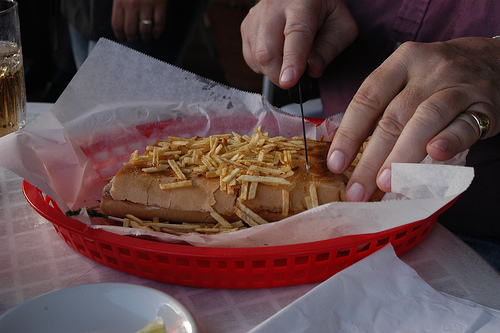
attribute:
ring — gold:
[470, 110, 492, 141]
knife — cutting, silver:
[296, 81, 313, 169]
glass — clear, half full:
[0, 3, 28, 140]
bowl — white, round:
[4, 282, 201, 331]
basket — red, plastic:
[22, 111, 469, 287]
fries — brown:
[134, 134, 340, 189]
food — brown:
[98, 131, 396, 227]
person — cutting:
[240, 1, 500, 202]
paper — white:
[1, 37, 319, 208]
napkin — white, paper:
[248, 243, 500, 332]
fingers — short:
[241, 1, 357, 90]